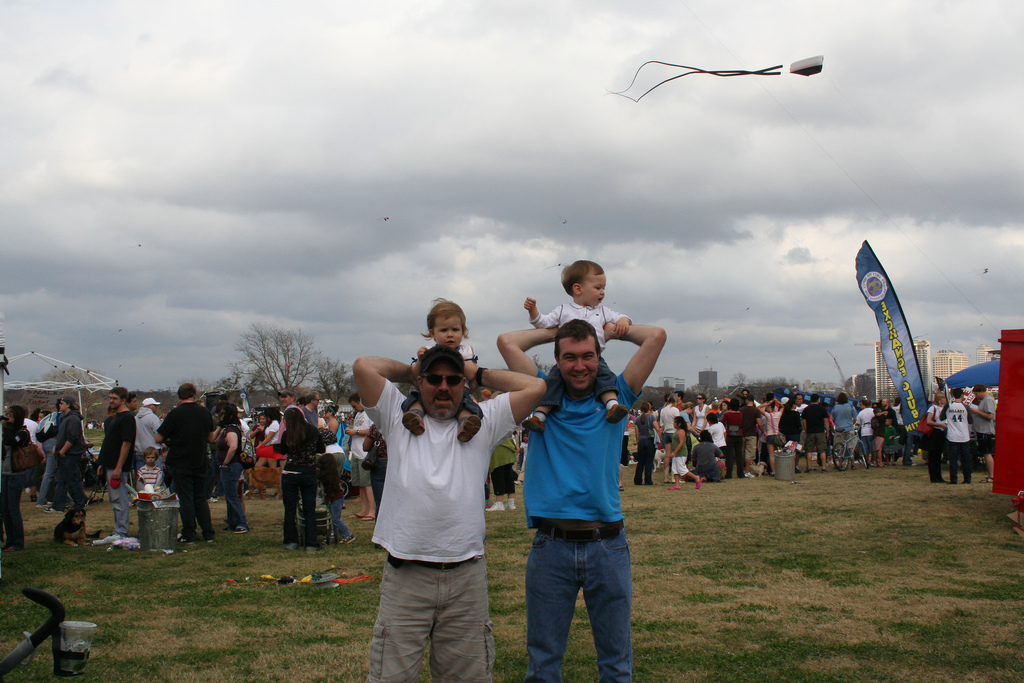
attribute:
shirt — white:
[354, 360, 539, 577]